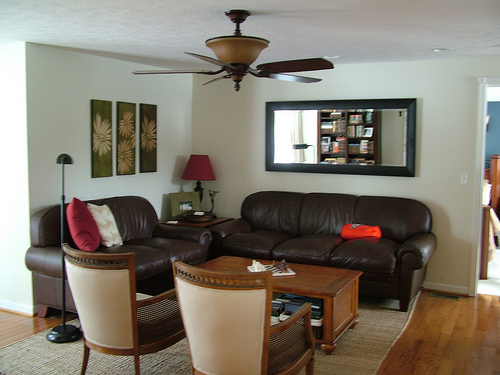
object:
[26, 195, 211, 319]
couch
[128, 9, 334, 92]
fan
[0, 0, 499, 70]
ceiling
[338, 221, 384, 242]
bag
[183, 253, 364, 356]
coffee table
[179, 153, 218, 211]
lamp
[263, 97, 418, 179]
mirror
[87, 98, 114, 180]
artwork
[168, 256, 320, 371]
chair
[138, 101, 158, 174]
picture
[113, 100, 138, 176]
picture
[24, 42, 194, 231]
wall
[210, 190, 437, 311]
sofa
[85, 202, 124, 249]
pillow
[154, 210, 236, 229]
night stand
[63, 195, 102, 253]
pillow